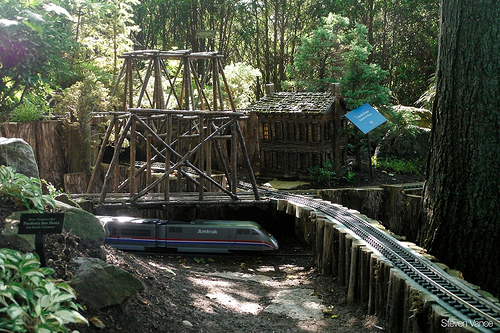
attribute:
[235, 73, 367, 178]
house — wooden 